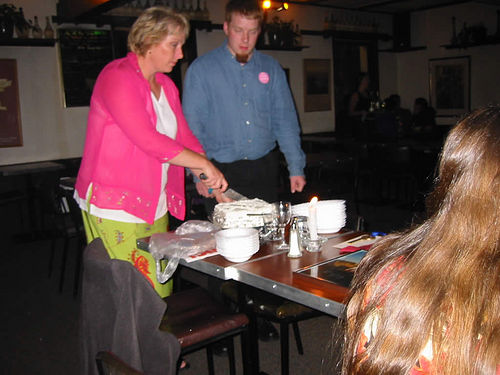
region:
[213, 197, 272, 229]
Fancy cake with icing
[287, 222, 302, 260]
Small clear salt shaker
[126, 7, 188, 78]
Head of woman cutting cake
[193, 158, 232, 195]
Hand of woman cutting cake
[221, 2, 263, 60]
Head of man in blue shirt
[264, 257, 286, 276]
Part of red serving table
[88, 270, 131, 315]
Part of gray jacket on chair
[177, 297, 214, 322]
Part of red chair seat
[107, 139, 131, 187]
Part of woman's bright pink jacket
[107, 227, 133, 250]
Part of woman's floral pants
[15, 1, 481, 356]
A cake is being cut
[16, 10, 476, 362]
People are enjoying a birthday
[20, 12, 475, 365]
A family is having a celebration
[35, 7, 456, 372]
A person is using a knife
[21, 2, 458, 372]
A cake is on a table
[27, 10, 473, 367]
Bowls and plates are stacked up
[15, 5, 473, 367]
A celebration in somebody's house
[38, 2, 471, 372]
People are enjoying their day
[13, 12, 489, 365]
The people are having a nice evening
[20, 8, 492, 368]
The people are in the living room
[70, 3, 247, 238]
Woman Cutting a Slice of Cake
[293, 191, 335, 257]
A Lit White Candle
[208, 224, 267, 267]
A Stack of Styrofoam Bowls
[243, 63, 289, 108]
A Pink Button Pinned to A Shirt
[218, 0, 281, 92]
A Red Headed Man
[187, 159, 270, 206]
A Hand Grasping a Knife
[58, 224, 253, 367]
A Coat Covering the Back of a Chair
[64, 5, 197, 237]
A Middle Aged Woman Wearing a Pink Shirt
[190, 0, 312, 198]
A Young Man Wearing a Blue Shirt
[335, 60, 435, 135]
A Waitress Carrying A Tray of Bottles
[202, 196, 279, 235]
cake on table top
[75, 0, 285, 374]
woman cutting cake on table top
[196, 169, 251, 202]
knife with wooden handle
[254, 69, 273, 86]
pink circle sticker on blue long seeve shirt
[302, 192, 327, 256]
lit white candle on table top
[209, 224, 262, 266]
stack of white bowls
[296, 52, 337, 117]
painting on wall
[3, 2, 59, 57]
shelf on white wall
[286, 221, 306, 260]
salt shaker on table top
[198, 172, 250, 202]
Large black handled knife a woman in pink is using.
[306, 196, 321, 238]
Thick white lit candle on a table.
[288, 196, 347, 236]
White stack of plates on a table.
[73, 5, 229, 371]
A woman with short blonde hair holding a knife in a pink shirt.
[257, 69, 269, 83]
Pink pin on a man's blue shirt.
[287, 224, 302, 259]
Clear salt shaker with silver lid and white salt inside.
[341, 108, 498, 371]
The long brown hair of the girl closest to the camera.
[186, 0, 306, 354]
A guy with a go-tee and a pink pin on his shirt.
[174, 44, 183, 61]
Nose on the face of a woman in a pink shirt.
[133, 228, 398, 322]
Two tables put together with cake and plates on top.